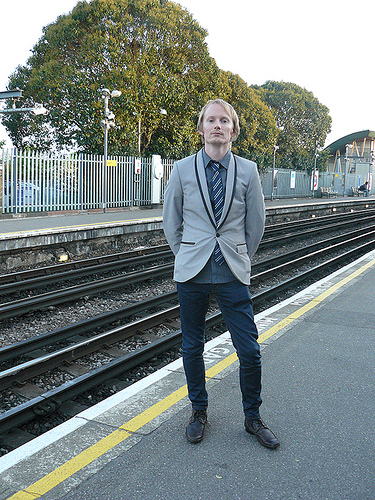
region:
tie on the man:
[203, 166, 233, 215]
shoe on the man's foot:
[184, 402, 210, 444]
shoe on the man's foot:
[242, 412, 281, 447]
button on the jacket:
[215, 233, 223, 238]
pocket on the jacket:
[237, 240, 247, 255]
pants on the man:
[178, 265, 265, 419]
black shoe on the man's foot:
[239, 415, 282, 451]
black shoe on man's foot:
[185, 402, 211, 442]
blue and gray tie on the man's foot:
[207, 162, 231, 268]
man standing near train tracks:
[159, 100, 283, 449]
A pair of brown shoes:
[186, 410, 281, 448]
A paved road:
[39, 260, 374, 497]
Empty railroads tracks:
[1, 204, 373, 435]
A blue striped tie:
[208, 163, 229, 263]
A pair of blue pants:
[173, 282, 262, 418]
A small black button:
[214, 233, 223, 238]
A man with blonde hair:
[195, 100, 240, 147]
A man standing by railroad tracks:
[162, 97, 280, 449]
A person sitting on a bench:
[357, 180, 371, 196]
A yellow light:
[57, 253, 69, 259]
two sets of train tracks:
[6, 209, 374, 429]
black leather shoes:
[185, 410, 277, 450]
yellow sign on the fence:
[107, 159, 119, 165]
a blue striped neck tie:
[211, 160, 227, 262]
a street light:
[99, 88, 118, 152]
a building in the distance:
[317, 127, 373, 166]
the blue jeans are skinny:
[176, 280, 263, 417]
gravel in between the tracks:
[13, 283, 165, 341]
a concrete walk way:
[1, 251, 371, 497]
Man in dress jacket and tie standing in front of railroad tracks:
[157, 96, 284, 450]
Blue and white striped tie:
[210, 160, 226, 268]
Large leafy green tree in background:
[3, 0, 281, 170]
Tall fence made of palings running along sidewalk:
[0, 146, 369, 212]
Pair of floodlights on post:
[98, 86, 123, 212]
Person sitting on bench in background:
[350, 180, 371, 198]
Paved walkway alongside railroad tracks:
[1, 195, 374, 236]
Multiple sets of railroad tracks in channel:
[1, 206, 373, 435]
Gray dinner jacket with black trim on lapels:
[158, 148, 266, 286]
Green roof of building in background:
[321, 129, 374, 157]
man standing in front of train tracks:
[148, 107, 304, 454]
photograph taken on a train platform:
[17, 91, 370, 480]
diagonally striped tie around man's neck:
[200, 159, 236, 264]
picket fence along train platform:
[16, 156, 316, 212]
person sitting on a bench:
[349, 178, 373, 196]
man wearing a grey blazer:
[161, 152, 271, 293]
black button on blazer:
[211, 230, 226, 245]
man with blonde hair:
[184, 83, 259, 157]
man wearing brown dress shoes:
[174, 409, 288, 454]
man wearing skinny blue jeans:
[169, 271, 271, 416]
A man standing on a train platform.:
[152, 90, 282, 452]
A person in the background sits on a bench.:
[351, 175, 371, 198]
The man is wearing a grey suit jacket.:
[154, 149, 275, 288]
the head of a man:
[194, 99, 241, 154]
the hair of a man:
[210, 99, 242, 123]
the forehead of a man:
[198, 105, 221, 113]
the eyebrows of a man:
[201, 108, 226, 119]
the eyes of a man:
[199, 115, 226, 123]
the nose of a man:
[214, 120, 218, 127]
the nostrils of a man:
[210, 121, 219, 129]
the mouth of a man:
[206, 124, 221, 135]